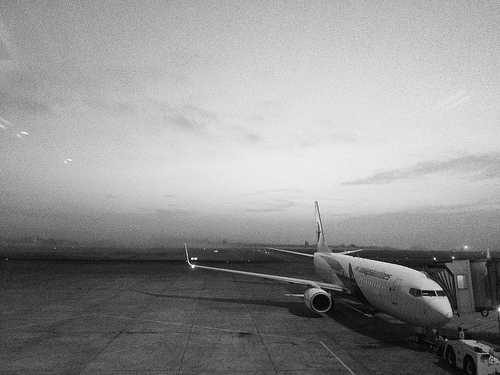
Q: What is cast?
A: Shadow.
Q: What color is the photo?
A: Black and white.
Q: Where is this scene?
A: Airport.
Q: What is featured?
A: A plane.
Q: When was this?
A: Daytime.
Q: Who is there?
A: No one.